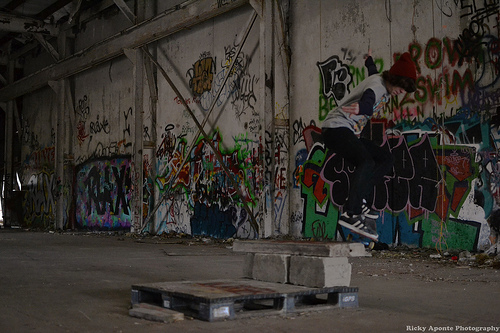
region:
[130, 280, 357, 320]
wood pallet in a warehouse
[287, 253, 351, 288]
white cinder block on top of a wood pallet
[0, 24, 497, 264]
graffiti painted on a warehouse wall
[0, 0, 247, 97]
concrete beam on the wall of a warehouse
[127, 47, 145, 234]
concrete columns in a warehouse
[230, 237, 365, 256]
a piece of a concrete slab on top of cinder blocks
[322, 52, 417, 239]
skateboarder jumping in a warehouse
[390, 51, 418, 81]
a young man wearing a burgundy knit cap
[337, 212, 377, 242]
a young man wearing gray and white skateboard shoes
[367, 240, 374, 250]
a white polyurethane skate board wheel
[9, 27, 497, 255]
Graffiti on wall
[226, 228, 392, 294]
Pieces of concrete on road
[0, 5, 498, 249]
Wall is made of wood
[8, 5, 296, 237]
Wall frame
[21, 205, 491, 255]
Trash beside the wall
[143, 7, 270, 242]
Two sticks crossed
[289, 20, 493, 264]
Graffiti has blue, black, green and red letters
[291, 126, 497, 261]
Big green letters on the background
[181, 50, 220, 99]
Yellow letters behind crossed sticks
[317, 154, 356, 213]
Black letter S with purple edges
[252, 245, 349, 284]
two cement blocks are on a pallet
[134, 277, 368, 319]
a pallet is on the ground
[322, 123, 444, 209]
the graffiti is black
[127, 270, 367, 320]
the pallet is wooden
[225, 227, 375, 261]
there is a board on the cement block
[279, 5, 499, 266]
there is graffiti behind the pallett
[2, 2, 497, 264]
the wall is cement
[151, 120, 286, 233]
the graffiti is o n the wall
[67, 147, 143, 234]
the graffiti is very colorful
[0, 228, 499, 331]
the ground is dusty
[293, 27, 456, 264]
Person riding skateboard outside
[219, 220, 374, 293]
three large concrete bricks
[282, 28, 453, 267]
Person wearing grey shirt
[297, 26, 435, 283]
Person wearing grey shirt and black pants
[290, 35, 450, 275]
Person wearing blue and white shoes and red hat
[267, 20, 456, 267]
Person wearing black pants and grey shirt with design on it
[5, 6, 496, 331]
the photo is clear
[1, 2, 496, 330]
the photo was taken during the day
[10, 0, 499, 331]
the photo was taken indoors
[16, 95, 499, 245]
the wall has graffiti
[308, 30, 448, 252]
the boy is wearing clothes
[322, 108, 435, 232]
the boy has black jeans